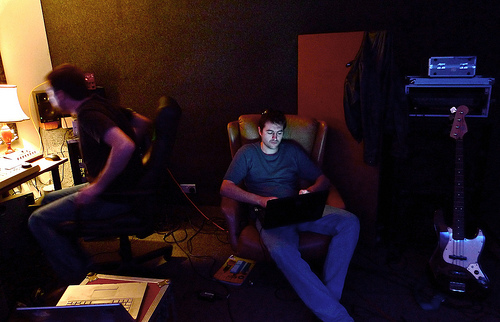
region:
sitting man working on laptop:
[223, 112, 328, 236]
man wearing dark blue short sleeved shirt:
[221, 108, 326, 197]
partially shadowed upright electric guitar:
[428, 152, 491, 314]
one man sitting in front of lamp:
[1, 61, 137, 193]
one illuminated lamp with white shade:
[0, 83, 29, 153]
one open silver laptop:
[13, 277, 155, 321]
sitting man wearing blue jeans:
[225, 105, 362, 317]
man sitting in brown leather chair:
[221, 111, 350, 262]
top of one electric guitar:
[446, 103, 471, 143]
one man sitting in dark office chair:
[28, 59, 172, 266]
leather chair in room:
[215, 108, 338, 266]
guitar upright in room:
[421, 95, 493, 311]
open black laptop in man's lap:
[249, 183, 340, 235]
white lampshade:
[0, 79, 32, 128]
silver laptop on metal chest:
[12, 265, 150, 319]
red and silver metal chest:
[68, 259, 179, 320]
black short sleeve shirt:
[64, 93, 140, 188]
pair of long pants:
[246, 203, 368, 319]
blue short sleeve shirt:
[222, 138, 327, 225]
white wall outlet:
[167, 178, 203, 198]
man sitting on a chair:
[205, 87, 359, 307]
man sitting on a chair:
[205, 87, 336, 261]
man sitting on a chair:
[203, 85, 363, 285]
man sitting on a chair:
[192, 82, 362, 259]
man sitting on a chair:
[190, 90, 372, 279]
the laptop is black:
[245, 182, 345, 244]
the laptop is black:
[250, 184, 325, 241]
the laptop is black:
[240, 167, 334, 234]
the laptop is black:
[234, 182, 354, 262]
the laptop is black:
[240, 159, 342, 248]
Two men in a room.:
[1, 3, 499, 318]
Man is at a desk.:
[1, 68, 180, 270]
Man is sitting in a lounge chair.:
[220, 103, 362, 304]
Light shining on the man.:
[228, 116, 320, 208]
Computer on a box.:
[9, 273, 167, 320]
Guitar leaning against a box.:
[424, 104, 496, 319]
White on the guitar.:
[441, 232, 498, 285]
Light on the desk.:
[0, 75, 39, 158]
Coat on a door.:
[341, 31, 419, 183]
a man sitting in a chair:
[187, 101, 397, 319]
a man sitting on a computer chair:
[19, 40, 204, 315]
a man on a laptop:
[234, 101, 383, 282]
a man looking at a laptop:
[179, 108, 352, 315]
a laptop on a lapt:
[197, 114, 374, 301]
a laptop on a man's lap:
[209, 116, 375, 316]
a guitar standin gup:
[405, 84, 492, 256]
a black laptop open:
[253, 151, 385, 290]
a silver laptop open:
[37, 236, 129, 313]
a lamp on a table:
[3, 72, 135, 272]